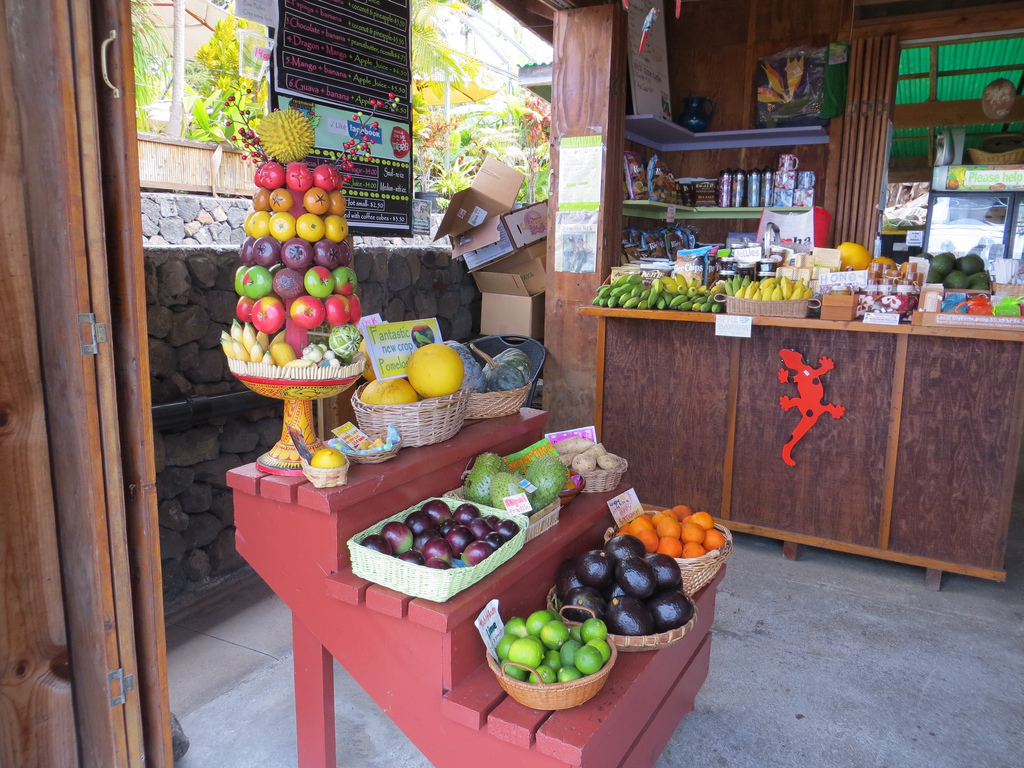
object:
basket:
[335, 467, 535, 614]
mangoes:
[371, 509, 423, 561]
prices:
[251, 12, 456, 243]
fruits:
[606, 550, 663, 596]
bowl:
[463, 594, 627, 724]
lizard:
[765, 323, 862, 496]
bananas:
[734, 281, 747, 298]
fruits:
[243, 287, 291, 335]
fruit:
[607, 475, 730, 567]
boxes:
[442, 196, 549, 277]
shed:
[865, 23, 1022, 117]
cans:
[711, 164, 736, 212]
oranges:
[678, 517, 710, 546]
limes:
[503, 623, 552, 674]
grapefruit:
[351, 332, 483, 411]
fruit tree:
[224, 100, 371, 491]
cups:
[774, 152, 803, 174]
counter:
[561, 254, 1022, 600]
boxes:
[427, 147, 536, 246]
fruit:
[455, 580, 639, 718]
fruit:
[603, 481, 746, 576]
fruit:
[339, 489, 538, 608]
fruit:
[447, 432, 582, 531]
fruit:
[340, 338, 475, 453]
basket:
[458, 580, 634, 727]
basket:
[331, 319, 482, 456]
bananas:
[767, 280, 786, 304]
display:
[170, 65, 754, 768]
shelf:
[599, 88, 858, 290]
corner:
[421, 54, 594, 458]